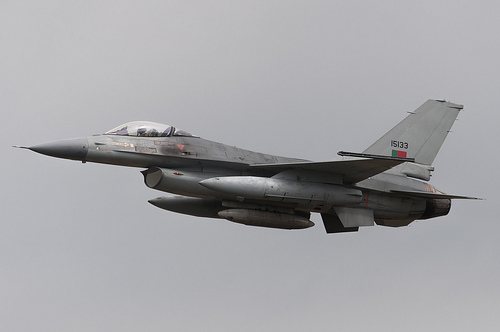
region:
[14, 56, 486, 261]
Fighter jet in the sky.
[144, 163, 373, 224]
Fuel tank on fighter jet.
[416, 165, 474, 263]
Rear Jet engine on fighter plane.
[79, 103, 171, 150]
Pilot in the cockpit.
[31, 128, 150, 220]
The nose of the fighter jet.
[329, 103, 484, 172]
Tail of the fighter jet.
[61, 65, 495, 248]
Grey fighter jet.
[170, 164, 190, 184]
Red light on the fighter jet.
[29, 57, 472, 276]
Military aircraft in the sky.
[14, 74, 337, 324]
Pilot flying in a fighter jet.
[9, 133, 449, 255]
gray jet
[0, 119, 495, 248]
gray jet in the sky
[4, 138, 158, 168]
point on the nose of the jet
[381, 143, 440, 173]
red and green rectangle on the tail of the jet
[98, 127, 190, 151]
pilot in the jet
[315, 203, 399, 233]
gray flaps on the jet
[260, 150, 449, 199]
wings on the jet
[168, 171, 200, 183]
red and green light on the underbelly of jet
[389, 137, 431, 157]
black numbers on jet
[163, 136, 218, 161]
fainted red triangle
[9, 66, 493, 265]
One large fighter jet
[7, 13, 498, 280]
Fighter jet flying in the air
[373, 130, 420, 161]
Jet number written on the tail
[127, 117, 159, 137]
Fighter pilot in the cockpit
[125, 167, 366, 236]
Fighter jet's weaponry on bottom of the jet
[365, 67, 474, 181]
Tail wing of the jet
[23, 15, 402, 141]
Overcast sky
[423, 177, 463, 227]
Rear engine of the jet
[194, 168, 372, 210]
One large missile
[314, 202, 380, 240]
Additional wings for being aerodynamics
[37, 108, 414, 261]
Silver jet in the air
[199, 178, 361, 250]
Jet armed with weapons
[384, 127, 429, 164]
Numbers 15133 on tail of jet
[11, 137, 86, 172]
Pointy front end of jet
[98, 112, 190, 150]
Clear glass hatch on top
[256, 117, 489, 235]
Wings on side of jet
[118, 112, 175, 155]
One person in jet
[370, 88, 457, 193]
Green and red color on jet tail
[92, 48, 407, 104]
Grayish sky out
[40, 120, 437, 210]
Large jet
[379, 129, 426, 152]
Black numbers that say 15133.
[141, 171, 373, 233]
Jet engines on jet.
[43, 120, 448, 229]
Jet flying through air.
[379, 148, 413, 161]
Red and green square.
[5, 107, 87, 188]
Tip of a jet plane.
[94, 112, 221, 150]
Cock pit of a jet.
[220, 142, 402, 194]
Wing of a jet.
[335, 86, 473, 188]
Tail of a jet.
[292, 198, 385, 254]
Drop hatch on a jet.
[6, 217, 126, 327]
Patch of gray sky.